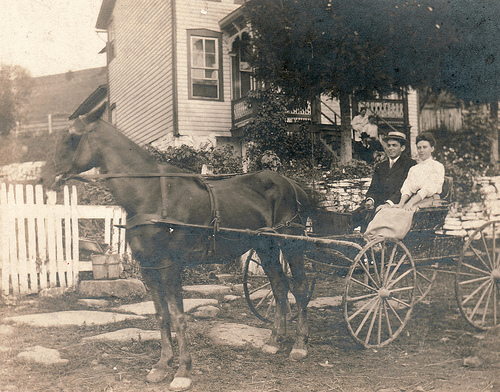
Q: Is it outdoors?
A: Yes, it is outdoors.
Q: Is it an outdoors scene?
A: Yes, it is outdoors.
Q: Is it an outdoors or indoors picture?
A: It is outdoors.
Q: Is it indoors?
A: No, it is outdoors.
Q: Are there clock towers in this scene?
A: No, there are no clock towers.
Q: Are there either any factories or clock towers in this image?
A: No, there are no clock towers or factories.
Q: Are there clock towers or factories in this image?
A: No, there are no clock towers or factories.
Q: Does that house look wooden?
A: Yes, the house is wooden.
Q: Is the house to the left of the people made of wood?
A: Yes, the house is made of wood.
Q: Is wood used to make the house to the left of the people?
A: Yes, the house is made of wood.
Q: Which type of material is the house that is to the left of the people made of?
A: The house is made of wood.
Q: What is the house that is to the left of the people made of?
A: The house is made of wood.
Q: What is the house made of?
A: The house is made of wood.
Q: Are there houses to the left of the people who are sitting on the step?
A: Yes, there is a house to the left of the people.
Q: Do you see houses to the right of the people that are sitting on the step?
A: No, the house is to the left of the people.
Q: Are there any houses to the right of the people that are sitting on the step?
A: No, the house is to the left of the people.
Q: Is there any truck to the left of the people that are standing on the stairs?
A: No, there is a house to the left of the people.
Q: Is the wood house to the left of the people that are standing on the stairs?
A: Yes, the house is to the left of the people.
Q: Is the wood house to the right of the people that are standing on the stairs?
A: No, the house is to the left of the people.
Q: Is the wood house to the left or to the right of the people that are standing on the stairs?
A: The house is to the left of the people.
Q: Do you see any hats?
A: Yes, there is a hat.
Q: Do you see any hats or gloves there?
A: Yes, there is a hat.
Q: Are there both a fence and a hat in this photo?
A: Yes, there are both a hat and a fence.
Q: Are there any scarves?
A: No, there are no scarves.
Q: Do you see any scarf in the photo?
A: No, there are no scarves.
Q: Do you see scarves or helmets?
A: No, there are no scarves or helmets.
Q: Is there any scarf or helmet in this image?
A: No, there are no scarves or helmets.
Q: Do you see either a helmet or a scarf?
A: No, there are no scarves or helmets.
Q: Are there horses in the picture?
A: Yes, there is a horse.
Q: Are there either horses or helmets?
A: Yes, there is a horse.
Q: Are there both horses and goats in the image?
A: No, there is a horse but no goats.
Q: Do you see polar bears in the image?
A: No, there are no polar bears.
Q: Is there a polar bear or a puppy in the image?
A: No, there are no polar bears or puppys.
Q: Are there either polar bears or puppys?
A: No, there are no polar bears or puppys.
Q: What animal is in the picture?
A: The animal is a horse.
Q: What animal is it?
A: The animal is a horse.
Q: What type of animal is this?
A: This is a horse.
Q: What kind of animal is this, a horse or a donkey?
A: This is a horse.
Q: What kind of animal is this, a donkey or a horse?
A: This is a horse.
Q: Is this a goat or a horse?
A: This is a horse.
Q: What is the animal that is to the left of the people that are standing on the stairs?
A: The animal is a horse.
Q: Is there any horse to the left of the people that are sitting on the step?
A: Yes, there is a horse to the left of the people.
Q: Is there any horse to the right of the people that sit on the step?
A: No, the horse is to the left of the people.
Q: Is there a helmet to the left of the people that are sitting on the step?
A: No, there is a horse to the left of the people.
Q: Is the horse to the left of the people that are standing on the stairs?
A: Yes, the horse is to the left of the people.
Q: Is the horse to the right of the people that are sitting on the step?
A: No, the horse is to the left of the people.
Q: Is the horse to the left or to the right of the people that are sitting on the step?
A: The horse is to the left of the people.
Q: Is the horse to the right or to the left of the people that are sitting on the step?
A: The horse is to the left of the people.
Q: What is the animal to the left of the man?
A: The animal is a horse.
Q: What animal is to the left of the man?
A: The animal is a horse.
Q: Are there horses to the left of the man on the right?
A: Yes, there is a horse to the left of the man.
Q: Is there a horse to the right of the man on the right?
A: No, the horse is to the left of the man.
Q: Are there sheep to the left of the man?
A: No, there is a horse to the left of the man.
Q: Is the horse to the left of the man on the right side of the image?
A: Yes, the horse is to the left of the man.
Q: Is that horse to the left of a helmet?
A: No, the horse is to the left of the man.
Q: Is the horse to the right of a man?
A: No, the horse is to the left of a man.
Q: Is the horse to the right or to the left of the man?
A: The horse is to the left of the man.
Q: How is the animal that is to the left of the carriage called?
A: The animal is a horse.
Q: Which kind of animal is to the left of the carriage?
A: The animal is a horse.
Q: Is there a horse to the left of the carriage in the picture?
A: Yes, there is a horse to the left of the carriage.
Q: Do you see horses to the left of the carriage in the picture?
A: Yes, there is a horse to the left of the carriage.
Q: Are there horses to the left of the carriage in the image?
A: Yes, there is a horse to the left of the carriage.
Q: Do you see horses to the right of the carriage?
A: No, the horse is to the left of the carriage.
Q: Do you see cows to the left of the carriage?
A: No, there is a horse to the left of the carriage.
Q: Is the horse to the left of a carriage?
A: Yes, the horse is to the left of a carriage.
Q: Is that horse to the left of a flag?
A: No, the horse is to the left of a carriage.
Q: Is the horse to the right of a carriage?
A: No, the horse is to the left of a carriage.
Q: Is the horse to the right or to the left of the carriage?
A: The horse is to the left of the carriage.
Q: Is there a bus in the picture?
A: No, there are no buses.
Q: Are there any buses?
A: No, there are no buses.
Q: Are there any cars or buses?
A: No, there are no buses or cars.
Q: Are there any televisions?
A: No, there are no televisions.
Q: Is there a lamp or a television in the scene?
A: No, there are no televisions or lamps.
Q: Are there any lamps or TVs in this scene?
A: No, there are no TVs or lamps.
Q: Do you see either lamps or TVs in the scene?
A: No, there are no TVs or lamps.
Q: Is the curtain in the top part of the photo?
A: Yes, the curtain is in the top of the image.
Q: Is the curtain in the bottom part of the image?
A: No, the curtain is in the top of the image.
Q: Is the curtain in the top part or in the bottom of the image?
A: The curtain is in the top of the image.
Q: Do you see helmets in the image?
A: No, there are no helmets.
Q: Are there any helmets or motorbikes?
A: No, there are no helmets or motorbikes.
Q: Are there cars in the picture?
A: No, there are no cars.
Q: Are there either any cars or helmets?
A: No, there are no cars or helmets.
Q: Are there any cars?
A: No, there are no cars.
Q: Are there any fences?
A: Yes, there is a fence.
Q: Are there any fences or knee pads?
A: Yes, there is a fence.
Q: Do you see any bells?
A: No, there are no bells.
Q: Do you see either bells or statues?
A: No, there are no bells or statues.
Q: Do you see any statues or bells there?
A: No, there are no bells or statues.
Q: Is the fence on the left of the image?
A: Yes, the fence is on the left of the image.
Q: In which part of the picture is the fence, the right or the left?
A: The fence is on the left of the image.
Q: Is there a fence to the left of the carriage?
A: Yes, there is a fence to the left of the carriage.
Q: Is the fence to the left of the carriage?
A: Yes, the fence is to the left of the carriage.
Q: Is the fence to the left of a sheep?
A: No, the fence is to the left of the carriage.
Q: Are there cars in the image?
A: No, there are no cars.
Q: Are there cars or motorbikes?
A: No, there are no cars or motorbikes.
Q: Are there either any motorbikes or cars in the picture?
A: No, there are no cars or motorbikes.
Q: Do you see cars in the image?
A: No, there are no cars.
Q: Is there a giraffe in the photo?
A: No, there are no giraffes.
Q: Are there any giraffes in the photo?
A: No, there are no giraffes.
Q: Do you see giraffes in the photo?
A: No, there are no giraffes.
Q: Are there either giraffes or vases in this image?
A: No, there are no giraffes or vases.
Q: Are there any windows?
A: Yes, there is a window.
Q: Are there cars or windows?
A: Yes, there is a window.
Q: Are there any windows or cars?
A: Yes, there is a window.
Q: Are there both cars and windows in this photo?
A: No, there is a window but no cars.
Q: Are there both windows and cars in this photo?
A: No, there is a window but no cars.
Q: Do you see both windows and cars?
A: No, there is a window but no cars.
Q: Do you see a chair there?
A: No, there are no chairs.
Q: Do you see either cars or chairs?
A: No, there are no chairs or cars.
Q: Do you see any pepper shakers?
A: No, there are no pepper shakers.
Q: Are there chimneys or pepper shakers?
A: No, there are no pepper shakers or chimneys.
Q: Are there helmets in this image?
A: No, there are no helmets.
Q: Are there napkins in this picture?
A: No, there are no napkins.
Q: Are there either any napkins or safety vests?
A: No, there are no napkins or safety vests.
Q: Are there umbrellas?
A: No, there are no umbrellas.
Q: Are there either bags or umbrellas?
A: No, there are no umbrellas or bags.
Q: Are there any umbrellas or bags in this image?
A: No, there are no umbrellas or bags.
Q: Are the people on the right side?
A: Yes, the people are on the right of the image.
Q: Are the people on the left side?
A: No, the people are on the right of the image.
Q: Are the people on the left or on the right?
A: The people are on the right of the image.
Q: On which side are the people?
A: The people are on the right of the image.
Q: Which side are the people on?
A: The people are on the right of the image.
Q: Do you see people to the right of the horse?
A: Yes, there are people to the right of the horse.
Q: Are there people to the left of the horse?
A: No, the people are to the right of the horse.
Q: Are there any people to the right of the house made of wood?
A: Yes, there are people to the right of the house.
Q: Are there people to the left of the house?
A: No, the people are to the right of the house.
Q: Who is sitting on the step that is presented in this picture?
A: The people are sitting on the step.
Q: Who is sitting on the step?
A: The people are sitting on the step.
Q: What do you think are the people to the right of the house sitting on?
A: The people are sitting on the step.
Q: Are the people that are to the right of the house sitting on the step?
A: Yes, the people are sitting on the step.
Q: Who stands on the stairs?
A: The people stand on the stairs.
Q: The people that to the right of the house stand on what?
A: The people stand on the stairs.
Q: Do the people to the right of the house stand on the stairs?
A: Yes, the people stand on the stairs.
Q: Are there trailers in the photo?
A: No, there are no trailers.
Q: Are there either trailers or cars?
A: No, there are no trailers or cars.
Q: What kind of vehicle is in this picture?
A: The vehicle is a carriage.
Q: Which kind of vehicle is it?
A: The vehicle is a carriage.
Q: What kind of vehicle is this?
A: This is a carriage.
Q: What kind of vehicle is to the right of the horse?
A: The vehicle is a carriage.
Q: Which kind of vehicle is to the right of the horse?
A: The vehicle is a carriage.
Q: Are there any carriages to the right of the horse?
A: Yes, there is a carriage to the right of the horse.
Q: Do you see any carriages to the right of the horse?
A: Yes, there is a carriage to the right of the horse.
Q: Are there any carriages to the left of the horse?
A: No, the carriage is to the right of the horse.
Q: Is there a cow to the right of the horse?
A: No, there is a carriage to the right of the horse.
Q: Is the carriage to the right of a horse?
A: Yes, the carriage is to the right of a horse.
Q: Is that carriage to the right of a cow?
A: No, the carriage is to the right of a horse.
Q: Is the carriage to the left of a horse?
A: No, the carriage is to the right of a horse.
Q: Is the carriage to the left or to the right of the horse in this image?
A: The carriage is to the right of the horse.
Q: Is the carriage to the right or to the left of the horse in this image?
A: The carriage is to the right of the horse.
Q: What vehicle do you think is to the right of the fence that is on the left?
A: The vehicle is a carriage.